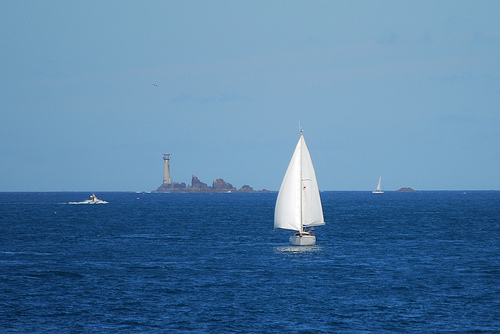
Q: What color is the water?
A: Blue.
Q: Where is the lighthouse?
A: On island.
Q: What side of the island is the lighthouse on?
A: Left.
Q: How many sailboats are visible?
A: 2.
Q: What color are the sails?
A: White.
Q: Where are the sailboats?
A: On the water.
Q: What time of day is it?
A: Daytime.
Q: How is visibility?
A: Good.